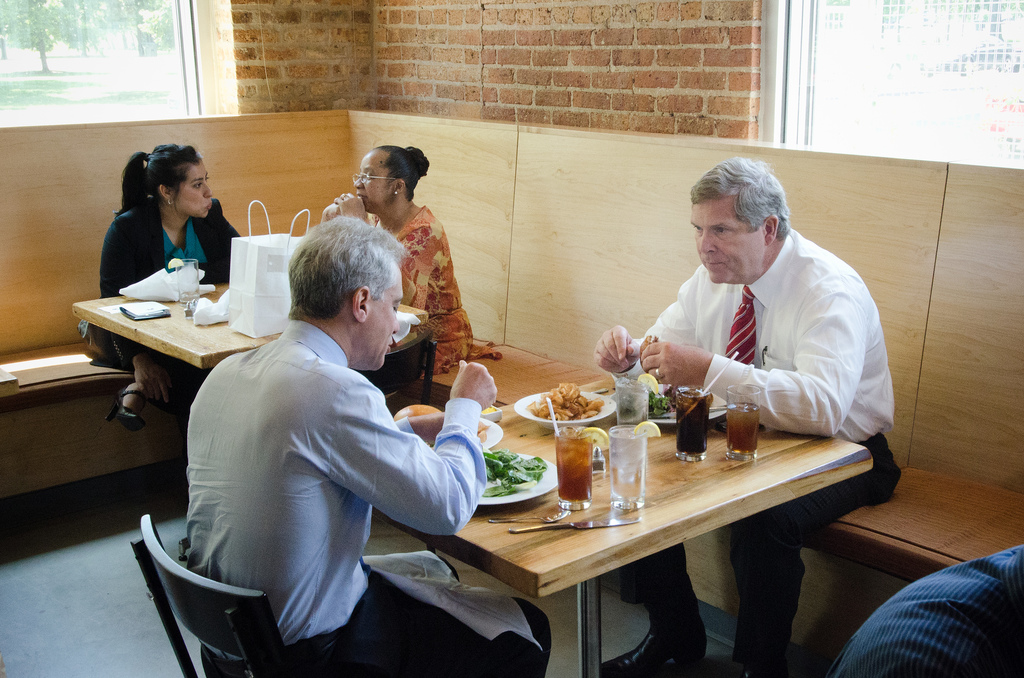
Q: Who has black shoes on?
A: A lady.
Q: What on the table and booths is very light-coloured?
A: The wood.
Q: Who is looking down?
A: One man.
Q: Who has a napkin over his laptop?
A: The one man.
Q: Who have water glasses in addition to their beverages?
A: Both men.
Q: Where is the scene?
A: At a diner.